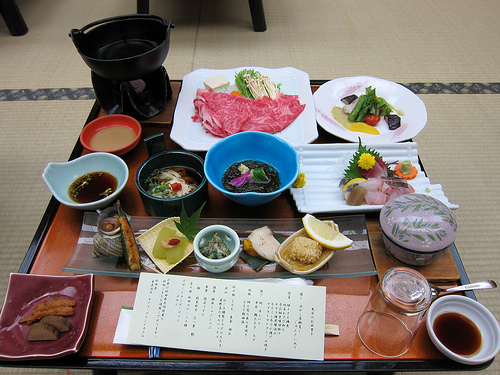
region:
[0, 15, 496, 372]
food on a tray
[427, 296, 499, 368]
dark sauce in a bowl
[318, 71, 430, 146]
food on a plate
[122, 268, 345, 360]
black writing on a white background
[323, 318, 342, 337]
top of a pair of chopsticks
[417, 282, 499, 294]
utensil laying on the tray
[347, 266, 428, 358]
glass that is upside down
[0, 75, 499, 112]
line on the floor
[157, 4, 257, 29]
shadow on the floor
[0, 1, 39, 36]
black leg of a piece of furniture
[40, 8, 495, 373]
japanese food on the table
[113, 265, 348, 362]
the menu on the table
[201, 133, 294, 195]
the blue bowl of caviar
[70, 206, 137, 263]
snail on the glass tray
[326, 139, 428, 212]
sushi on the fluted plate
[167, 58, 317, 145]
the square plate with sliced meat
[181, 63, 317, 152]
the square plate with mushrooms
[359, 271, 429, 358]
the glass is over turned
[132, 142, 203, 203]
the bowl of soup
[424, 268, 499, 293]
the spoon on the table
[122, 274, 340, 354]
A bill for the meal.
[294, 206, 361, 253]
A slice of lemon.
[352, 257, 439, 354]
A clear glass waiting to be used.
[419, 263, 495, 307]
A spoon on the tray.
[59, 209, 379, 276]
A glass dish of food.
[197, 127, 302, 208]
Blue bowl of food.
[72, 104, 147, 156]
Orange bowl full of sauce.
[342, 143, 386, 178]
Small yellow flower for decoration.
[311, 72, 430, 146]
Vegetables on a white plate.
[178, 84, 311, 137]
Piece of meat on a plate.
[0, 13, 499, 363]
an array of Asian delicacies on a table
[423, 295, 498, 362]
a small bowl of soy sauce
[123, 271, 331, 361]
a printed restaurant bill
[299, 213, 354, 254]
a small wedge of lemon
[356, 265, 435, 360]
a small glass turned upside down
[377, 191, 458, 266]
an intricately designed ceramic dish and lid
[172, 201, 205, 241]
a decorative green leaf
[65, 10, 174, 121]
a small black cooking device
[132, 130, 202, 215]
a small bowl of Asian style soup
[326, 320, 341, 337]
the ends of a pair of chopsticks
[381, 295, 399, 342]
the meat is pinkthe glass is clear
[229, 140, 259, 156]
the bowl is blue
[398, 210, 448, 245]
the lid has green leaves on it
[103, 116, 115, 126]
the bowl is orange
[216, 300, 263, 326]
the receipt is white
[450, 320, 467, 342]
the liquid is brown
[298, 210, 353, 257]
the lemon is yellow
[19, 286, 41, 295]
the plate is purple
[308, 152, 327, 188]
the plate is ridged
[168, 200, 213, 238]
the leaf is green